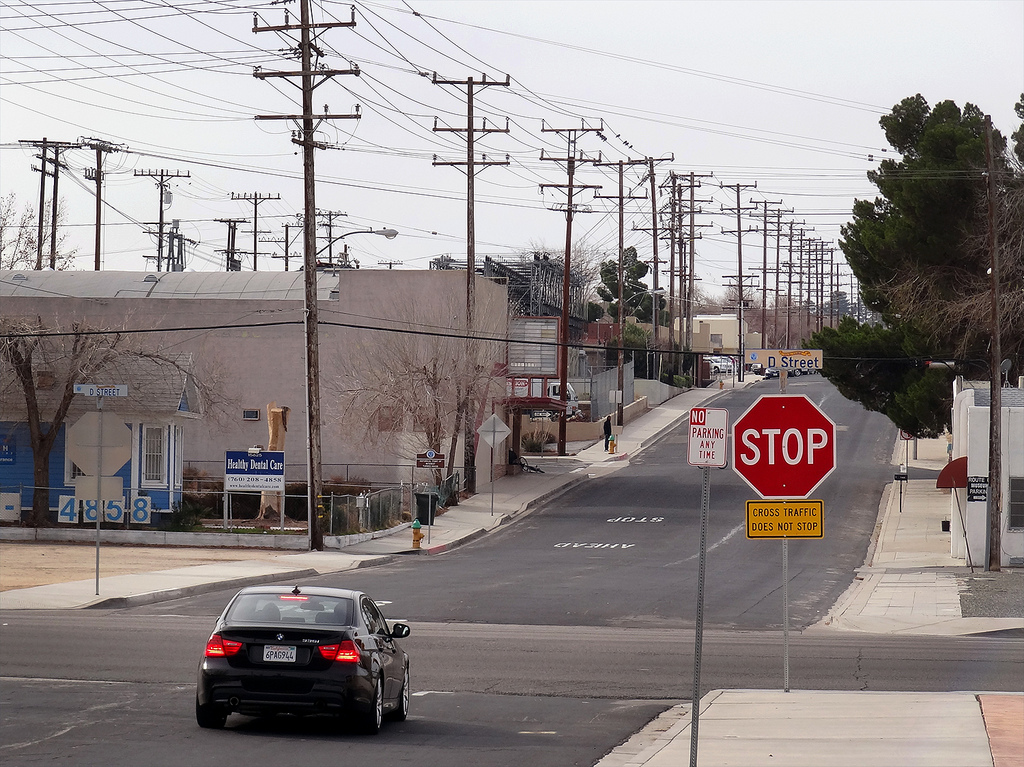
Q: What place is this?
A: It is a city.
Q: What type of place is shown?
A: It is a city.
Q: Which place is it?
A: It is a city.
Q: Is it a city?
A: Yes, it is a city.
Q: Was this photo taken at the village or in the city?
A: It was taken at the city.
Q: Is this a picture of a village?
A: No, the picture is showing a city.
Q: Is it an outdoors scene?
A: Yes, it is outdoors.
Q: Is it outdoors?
A: Yes, it is outdoors.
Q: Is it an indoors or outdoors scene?
A: It is outdoors.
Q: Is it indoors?
A: No, it is outdoors.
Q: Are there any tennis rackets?
A: No, there are no tennis rackets.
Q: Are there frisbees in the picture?
A: No, there are no frisbees.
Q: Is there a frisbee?
A: No, there are no frisbees.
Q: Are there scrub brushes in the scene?
A: No, there are no scrub brushes.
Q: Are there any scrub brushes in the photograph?
A: No, there are no scrub brushes.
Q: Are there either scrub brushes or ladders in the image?
A: No, there are no scrub brushes or ladders.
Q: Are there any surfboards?
A: No, there are no surfboards.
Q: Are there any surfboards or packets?
A: No, there are no surfboards or packets.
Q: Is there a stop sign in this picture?
A: Yes, there is a stop sign.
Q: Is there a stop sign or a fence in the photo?
A: Yes, there is a stop sign.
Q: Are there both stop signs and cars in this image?
A: Yes, there are both a stop sign and a car.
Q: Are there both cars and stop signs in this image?
A: Yes, there are both a stop sign and a car.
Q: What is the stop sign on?
A: The stop sign is on the pole.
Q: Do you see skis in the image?
A: No, there are no skis.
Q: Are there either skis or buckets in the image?
A: No, there are no skis or buckets.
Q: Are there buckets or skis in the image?
A: No, there are no skis or buckets.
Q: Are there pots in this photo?
A: No, there are no pots.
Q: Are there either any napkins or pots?
A: No, there are no pots or napkins.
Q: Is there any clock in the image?
A: No, there are no clocks.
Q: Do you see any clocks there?
A: No, there are no clocks.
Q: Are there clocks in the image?
A: No, there are no clocks.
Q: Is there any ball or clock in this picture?
A: No, there are no clocks or balls.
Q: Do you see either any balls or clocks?
A: No, there are no clocks or balls.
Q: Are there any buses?
A: No, there are no buses.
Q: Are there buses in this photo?
A: No, there are no buses.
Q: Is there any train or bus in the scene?
A: No, there are no buses or trains.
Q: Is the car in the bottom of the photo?
A: Yes, the car is in the bottom of the image.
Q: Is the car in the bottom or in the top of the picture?
A: The car is in the bottom of the image.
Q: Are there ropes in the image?
A: No, there are no ropes.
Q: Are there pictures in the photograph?
A: No, there are no pictures.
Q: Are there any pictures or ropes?
A: No, there are no pictures or ropes.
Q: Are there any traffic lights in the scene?
A: No, there are no traffic lights.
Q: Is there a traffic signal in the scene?
A: No, there are no traffic lights.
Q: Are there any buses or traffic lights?
A: No, there are no traffic lights or buses.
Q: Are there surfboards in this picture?
A: No, there are no surfboards.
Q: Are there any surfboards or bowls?
A: No, there are no surfboards or bowls.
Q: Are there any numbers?
A: Yes, there are numbers.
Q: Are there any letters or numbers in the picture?
A: Yes, there are numbers.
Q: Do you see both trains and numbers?
A: No, there are numbers but no trains.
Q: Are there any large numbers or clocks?
A: Yes, there are large numbers.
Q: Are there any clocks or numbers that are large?
A: Yes, the numbers are large.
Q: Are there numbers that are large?
A: Yes, there are large numbers.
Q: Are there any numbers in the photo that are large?
A: Yes, there are numbers that are large.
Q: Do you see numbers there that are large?
A: Yes, there are numbers that are large.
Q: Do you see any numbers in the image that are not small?
A: Yes, there are large numbers.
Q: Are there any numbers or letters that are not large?
A: No, there are numbers but they are large.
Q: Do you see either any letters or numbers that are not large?
A: No, there are numbers but they are large.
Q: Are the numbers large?
A: Yes, the numbers are large.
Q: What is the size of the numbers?
A: The numbers are large.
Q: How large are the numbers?
A: The numbers are large.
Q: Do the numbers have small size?
A: No, the numbers are large.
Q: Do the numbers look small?
A: No, the numbers are large.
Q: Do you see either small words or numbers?
A: No, there are numbers but they are large.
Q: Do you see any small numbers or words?
A: No, there are numbers but they are large.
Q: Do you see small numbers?
A: No, there are numbers but they are large.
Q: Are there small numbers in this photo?
A: No, there are numbers but they are large.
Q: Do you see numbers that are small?
A: No, there are numbers but they are large.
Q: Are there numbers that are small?
A: No, there are numbers but they are large.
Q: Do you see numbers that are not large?
A: No, there are numbers but they are large.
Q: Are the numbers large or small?
A: The numbers are large.